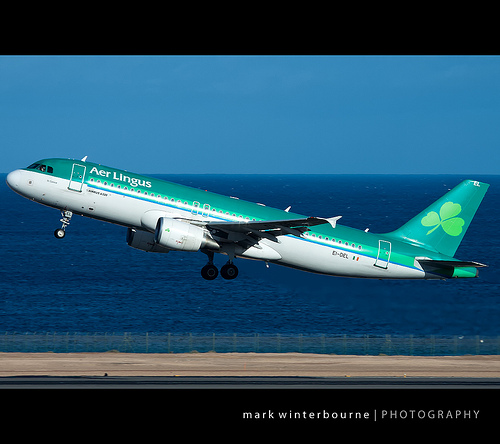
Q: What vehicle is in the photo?
A: An airplane.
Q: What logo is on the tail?
A: A three leaf clover.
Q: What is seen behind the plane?
A: Water.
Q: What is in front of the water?
A: A fence.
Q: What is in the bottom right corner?
A: A watermark.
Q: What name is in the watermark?
A: Mark Winterbourne.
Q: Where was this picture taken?
A: At an airport.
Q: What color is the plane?
A: The plane is white and blue.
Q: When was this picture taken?
A: It was taken in the day time.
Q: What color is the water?
A: The water is blue.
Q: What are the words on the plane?
A: The words are aer lingus.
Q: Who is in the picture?
A: Nobody is in the picture.